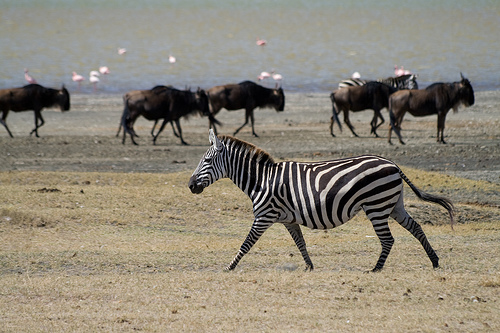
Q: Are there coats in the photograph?
A: Yes, there is a coat.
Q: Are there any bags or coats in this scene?
A: Yes, there is a coat.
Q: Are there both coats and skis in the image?
A: No, there is a coat but no skis.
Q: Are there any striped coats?
A: Yes, there is a striped coat.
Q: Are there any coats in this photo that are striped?
A: Yes, there is a coat that is striped.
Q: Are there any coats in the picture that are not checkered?
A: Yes, there is a striped coat.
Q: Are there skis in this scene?
A: No, there are no skis.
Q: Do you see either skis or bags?
A: No, there are no skis or bags.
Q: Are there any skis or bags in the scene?
A: No, there are no skis or bags.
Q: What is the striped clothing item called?
A: The clothing item is a coat.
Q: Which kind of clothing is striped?
A: The clothing is a coat.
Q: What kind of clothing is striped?
A: The clothing is a coat.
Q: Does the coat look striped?
A: Yes, the coat is striped.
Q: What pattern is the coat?
A: The coat is striped.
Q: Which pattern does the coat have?
A: The coat has striped pattern.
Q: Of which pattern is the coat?
A: The coat is striped.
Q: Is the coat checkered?
A: No, the coat is striped.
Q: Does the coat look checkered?
A: No, the coat is striped.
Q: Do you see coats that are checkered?
A: No, there is a coat but it is striped.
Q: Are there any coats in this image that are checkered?
A: No, there is a coat but it is striped.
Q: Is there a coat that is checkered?
A: No, there is a coat but it is striped.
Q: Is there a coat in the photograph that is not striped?
A: No, there is a coat but it is striped.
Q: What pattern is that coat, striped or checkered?
A: The coat is striped.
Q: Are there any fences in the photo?
A: No, there are no fences.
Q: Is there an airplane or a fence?
A: No, there are no fences or airplanes.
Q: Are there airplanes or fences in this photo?
A: No, there are no fences or airplanes.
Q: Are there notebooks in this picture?
A: No, there are no notebooks.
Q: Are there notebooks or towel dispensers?
A: No, there are no notebooks or towel dispensers.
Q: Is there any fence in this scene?
A: No, there are no fences.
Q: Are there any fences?
A: No, there are no fences.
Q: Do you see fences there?
A: No, there are no fences.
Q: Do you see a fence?
A: No, there are no fences.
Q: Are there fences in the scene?
A: No, there are no fences.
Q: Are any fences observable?
A: No, there are no fences.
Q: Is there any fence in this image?
A: No, there are no fences.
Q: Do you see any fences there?
A: No, there are no fences.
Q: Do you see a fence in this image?
A: No, there are no fences.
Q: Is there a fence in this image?
A: No, there are no fences.